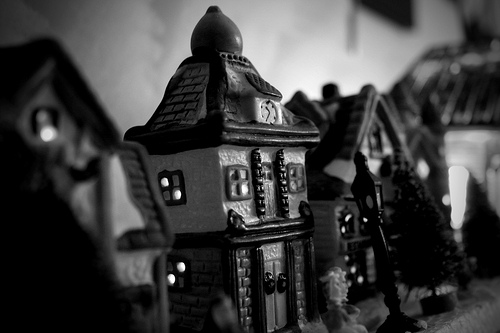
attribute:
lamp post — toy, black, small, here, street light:
[351, 154, 427, 332]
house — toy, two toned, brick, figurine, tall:
[124, 16, 341, 332]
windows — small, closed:
[159, 157, 309, 208]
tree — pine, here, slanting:
[387, 151, 465, 315]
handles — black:
[265, 270, 285, 295]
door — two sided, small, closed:
[264, 260, 293, 332]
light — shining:
[160, 177, 185, 203]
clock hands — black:
[263, 104, 272, 125]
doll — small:
[205, 295, 241, 332]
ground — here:
[322, 275, 500, 332]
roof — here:
[142, 52, 301, 128]